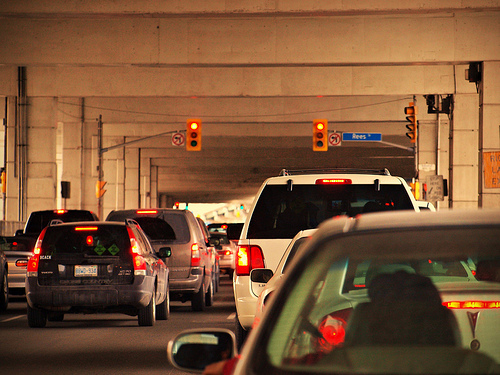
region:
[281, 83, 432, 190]
street light is lit yellow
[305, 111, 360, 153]
street light has sign next to it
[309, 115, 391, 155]
blue street sign next to stop light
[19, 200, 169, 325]
car has break lights on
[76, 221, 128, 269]
car has green sign in window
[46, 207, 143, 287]
car has two sing in window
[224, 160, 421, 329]
vehicle is square in shape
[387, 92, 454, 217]
stop lights line street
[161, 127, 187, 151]
sign has red marking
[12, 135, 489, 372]
multiple cars on street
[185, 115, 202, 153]
Yellow traffic light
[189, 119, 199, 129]
Red light on a traffic light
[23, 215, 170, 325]
Dirty station wagon stopped at an intersection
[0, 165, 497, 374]
Vehicles stopped at an intersection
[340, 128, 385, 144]
Blue street sign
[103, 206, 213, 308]
Dirty gray minivan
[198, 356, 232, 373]
Persons hand sticking out of a car window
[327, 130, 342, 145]
White no left turn sign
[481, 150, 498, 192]
Square yellow traffic sign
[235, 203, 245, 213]
Green traffic light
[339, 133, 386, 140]
Blue street sign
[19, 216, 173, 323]
Black volvo car with green stickers on windows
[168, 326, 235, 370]
Left rear view mirror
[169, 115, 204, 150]
Red traffic light with no left turn sign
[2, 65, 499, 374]
Under bridge view of tunnel with cars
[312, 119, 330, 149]
Right red traffic light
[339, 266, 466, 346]
Backseat view of driver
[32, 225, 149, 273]
Pair of red lights stopped at traffic light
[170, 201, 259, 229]
Outside view of tunnel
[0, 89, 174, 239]
Pillars holding bridge tunnel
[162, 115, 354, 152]
two red traffic lights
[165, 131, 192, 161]
red and black sign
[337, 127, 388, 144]
white and blue sign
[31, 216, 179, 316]
grey car is stopped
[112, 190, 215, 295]
grey hybrid in front of grey car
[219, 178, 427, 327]
white van is stopped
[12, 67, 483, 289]
cars under grey bridge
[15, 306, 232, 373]
road is dark grey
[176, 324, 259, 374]
grey driver's side mirror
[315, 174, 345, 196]
red light on top of white van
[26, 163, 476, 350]
many cars stopped on a street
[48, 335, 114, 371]
black asphalt of the road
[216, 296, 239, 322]
white line painted on the road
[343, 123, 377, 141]
a blue street marker on a post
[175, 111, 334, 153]
two yellow stoplights over the street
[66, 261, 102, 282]
white license plate with blue lettering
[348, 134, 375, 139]
white lettering on a blue sign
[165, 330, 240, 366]
the grey side mirror of a car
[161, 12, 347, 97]
grey stone supports of a tunnel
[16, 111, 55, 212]
grey stone column of the tunnel